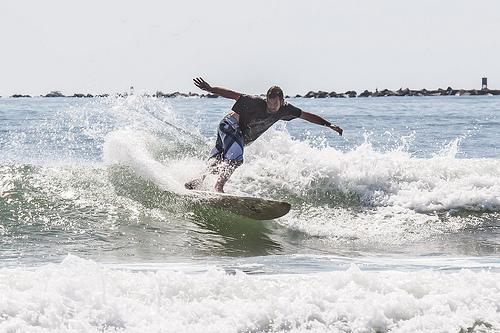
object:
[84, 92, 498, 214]
waves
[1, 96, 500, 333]
water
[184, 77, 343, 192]
man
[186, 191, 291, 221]
surfboard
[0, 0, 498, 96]
sky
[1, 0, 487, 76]
clouds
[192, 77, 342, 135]
arms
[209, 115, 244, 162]
shorts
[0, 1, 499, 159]
background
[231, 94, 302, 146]
shirt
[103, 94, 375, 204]
wave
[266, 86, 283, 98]
hair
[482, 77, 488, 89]
building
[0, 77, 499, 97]
shoreline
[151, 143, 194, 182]
wake